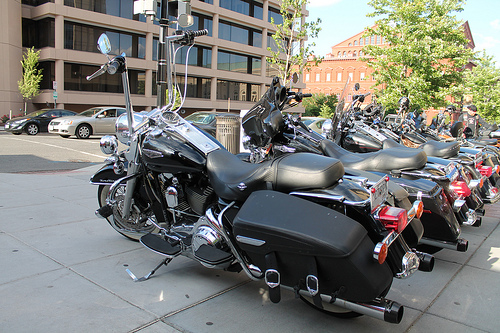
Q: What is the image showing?
A: It is showing an office.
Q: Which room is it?
A: It is an office.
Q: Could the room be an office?
A: Yes, it is an office.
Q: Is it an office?
A: Yes, it is an office.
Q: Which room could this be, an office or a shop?
A: It is an office.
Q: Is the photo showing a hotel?
A: No, the picture is showing an office.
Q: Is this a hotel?
A: No, it is an office.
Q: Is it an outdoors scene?
A: Yes, it is outdoors.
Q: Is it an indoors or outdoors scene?
A: It is outdoors.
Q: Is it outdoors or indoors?
A: It is outdoors.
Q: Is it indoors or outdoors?
A: It is outdoors.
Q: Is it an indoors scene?
A: No, it is outdoors.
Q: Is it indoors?
A: No, it is outdoors.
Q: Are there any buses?
A: No, there are no buses.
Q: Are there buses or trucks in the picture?
A: No, there are no buses or trucks.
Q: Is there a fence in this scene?
A: No, there are no fences.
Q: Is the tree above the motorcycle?
A: Yes, the tree is above the motorcycle.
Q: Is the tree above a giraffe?
A: No, the tree is above the motorcycle.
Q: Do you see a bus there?
A: No, there are no buses.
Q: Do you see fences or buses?
A: No, there are no buses or fences.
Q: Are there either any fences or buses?
A: No, there are no buses or fences.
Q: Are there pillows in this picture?
A: No, there are no pillows.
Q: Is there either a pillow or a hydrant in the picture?
A: No, there are no pillows or fire hydrants.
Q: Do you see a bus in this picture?
A: No, there are no buses.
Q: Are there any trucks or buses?
A: No, there are no buses or trucks.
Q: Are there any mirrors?
A: Yes, there is a mirror.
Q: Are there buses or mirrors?
A: Yes, there is a mirror.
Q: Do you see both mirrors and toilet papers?
A: No, there is a mirror but no toilet papers.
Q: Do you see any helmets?
A: No, there are no helmets.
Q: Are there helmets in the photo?
A: No, there are no helmets.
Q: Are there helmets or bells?
A: No, there are no helmets or bells.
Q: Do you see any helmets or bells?
A: No, there are no helmets or bells.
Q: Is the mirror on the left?
A: Yes, the mirror is on the left of the image.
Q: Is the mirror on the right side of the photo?
A: No, the mirror is on the left of the image.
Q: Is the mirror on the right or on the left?
A: The mirror is on the left of the image.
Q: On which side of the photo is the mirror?
A: The mirror is on the left of the image.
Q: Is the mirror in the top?
A: Yes, the mirror is in the top of the image.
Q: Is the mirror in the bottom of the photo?
A: No, the mirror is in the top of the image.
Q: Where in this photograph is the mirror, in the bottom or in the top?
A: The mirror is in the top of the image.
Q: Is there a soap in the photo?
A: No, there are no soaps.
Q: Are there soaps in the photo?
A: No, there are no soaps.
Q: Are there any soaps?
A: No, there are no soaps.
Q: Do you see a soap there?
A: No, there are no soaps.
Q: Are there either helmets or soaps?
A: No, there are no soaps or helmets.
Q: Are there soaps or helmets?
A: No, there are no soaps or helmets.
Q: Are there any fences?
A: No, there are no fences.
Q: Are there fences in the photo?
A: No, there are no fences.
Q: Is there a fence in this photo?
A: No, there are no fences.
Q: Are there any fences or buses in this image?
A: No, there are no fences or buses.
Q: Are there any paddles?
A: No, there are no paddles.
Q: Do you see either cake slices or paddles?
A: No, there are no paddles or cake slices.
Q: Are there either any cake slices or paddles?
A: No, there are no paddles or cake slices.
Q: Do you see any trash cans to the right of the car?
A: Yes, there is a trash can to the right of the car.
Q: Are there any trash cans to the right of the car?
A: Yes, there is a trash can to the right of the car.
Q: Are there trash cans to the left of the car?
A: No, the trash can is to the right of the car.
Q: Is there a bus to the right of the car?
A: No, there is a trash can to the right of the car.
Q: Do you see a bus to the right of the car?
A: No, there is a trash can to the right of the car.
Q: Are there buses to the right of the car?
A: No, there is a trash can to the right of the car.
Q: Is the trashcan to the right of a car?
A: Yes, the trashcan is to the right of a car.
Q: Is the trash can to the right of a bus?
A: No, the trash can is to the right of a car.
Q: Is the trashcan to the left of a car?
A: No, the trashcan is to the right of a car.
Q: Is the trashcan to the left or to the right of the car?
A: The trashcan is to the right of the car.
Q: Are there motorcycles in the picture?
A: Yes, there is a motorcycle.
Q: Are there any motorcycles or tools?
A: Yes, there is a motorcycle.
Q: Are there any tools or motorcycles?
A: Yes, there is a motorcycle.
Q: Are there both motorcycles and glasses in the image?
A: No, there is a motorcycle but no glasses.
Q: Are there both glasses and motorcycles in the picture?
A: No, there is a motorcycle but no glasses.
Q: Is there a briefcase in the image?
A: No, there are no briefcases.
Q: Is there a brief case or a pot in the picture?
A: No, there are no briefcases or pots.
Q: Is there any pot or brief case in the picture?
A: No, there are no briefcases or pots.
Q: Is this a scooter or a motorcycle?
A: This is a motorcycle.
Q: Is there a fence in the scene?
A: No, there are no fences.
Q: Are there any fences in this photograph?
A: No, there are no fences.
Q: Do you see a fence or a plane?
A: No, there are no fences or airplanes.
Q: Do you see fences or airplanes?
A: No, there are no fences or airplanes.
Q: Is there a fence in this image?
A: No, there are no fences.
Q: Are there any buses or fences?
A: No, there are no fences or buses.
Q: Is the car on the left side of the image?
A: Yes, the car is on the left of the image.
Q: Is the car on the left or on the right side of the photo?
A: The car is on the left of the image.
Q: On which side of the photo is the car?
A: The car is on the left of the image.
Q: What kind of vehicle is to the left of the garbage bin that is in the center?
A: The vehicle is a car.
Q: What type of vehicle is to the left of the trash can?
A: The vehicle is a car.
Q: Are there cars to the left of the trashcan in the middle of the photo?
A: Yes, there is a car to the left of the garbage bin.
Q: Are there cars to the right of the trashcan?
A: No, the car is to the left of the trashcan.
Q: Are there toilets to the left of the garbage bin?
A: No, there is a car to the left of the garbage bin.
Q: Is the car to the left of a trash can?
A: Yes, the car is to the left of a trash can.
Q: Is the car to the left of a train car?
A: No, the car is to the left of a trash can.